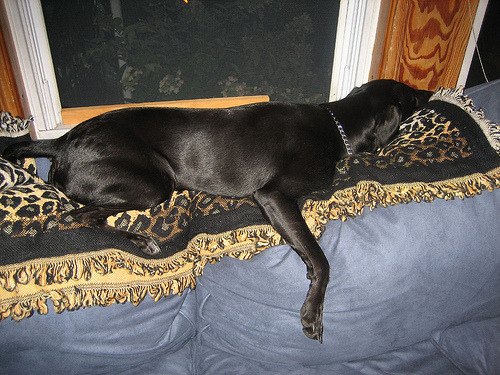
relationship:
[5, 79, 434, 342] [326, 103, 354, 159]
dog has a chain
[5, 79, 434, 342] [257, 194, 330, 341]
dog has a leg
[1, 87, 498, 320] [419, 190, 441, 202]
blanket has tassles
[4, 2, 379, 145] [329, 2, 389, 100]
window has a sill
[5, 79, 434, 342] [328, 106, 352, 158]
dog has a collar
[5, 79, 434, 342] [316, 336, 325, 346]
dog has claws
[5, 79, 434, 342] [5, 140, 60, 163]
dog has a tail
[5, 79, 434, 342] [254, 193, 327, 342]
dog has a arm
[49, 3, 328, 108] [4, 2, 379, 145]
plant in window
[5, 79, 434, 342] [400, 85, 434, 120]
dog has a face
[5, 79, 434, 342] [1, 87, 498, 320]
dog has a blanket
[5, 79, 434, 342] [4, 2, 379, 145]
dog next to a window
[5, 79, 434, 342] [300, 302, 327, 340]
dog has a paw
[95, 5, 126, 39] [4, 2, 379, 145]
leaves outside of window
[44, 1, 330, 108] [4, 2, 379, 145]
tree outside of window